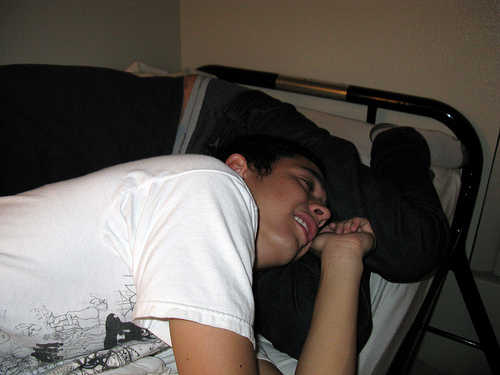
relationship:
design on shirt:
[2, 285, 171, 371] [2, 152, 276, 371]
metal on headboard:
[274, 73, 351, 104] [193, 64, 483, 370]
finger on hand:
[319, 217, 373, 234] [310, 214, 375, 252]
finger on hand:
[347, 216, 369, 234] [310, 214, 375, 252]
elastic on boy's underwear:
[173, 92, 204, 154] [172, 72, 249, 155]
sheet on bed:
[286, 100, 464, 373] [124, 60, 497, 372]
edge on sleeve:
[133, 301, 257, 349] [129, 181, 261, 344]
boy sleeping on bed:
[0, 136, 373, 375] [6, 61, 475, 370]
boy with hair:
[0, 136, 373, 375] [214, 130, 329, 175]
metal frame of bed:
[198, 60, 498, 370] [6, 61, 475, 370]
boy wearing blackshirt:
[0, 136, 373, 375] [3, 61, 158, 152]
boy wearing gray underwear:
[0, 136, 373, 375] [173, 70, 254, 163]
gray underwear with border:
[173, 70, 254, 163] [166, 72, 216, 152]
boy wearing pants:
[0, 136, 373, 375] [202, 90, 454, 356]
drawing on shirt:
[21, 300, 143, 372] [2, 152, 276, 371]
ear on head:
[224, 153, 246, 178] [216, 144, 330, 274]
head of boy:
[216, 144, 330, 274] [2, 118, 377, 372]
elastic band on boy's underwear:
[170, 70, 218, 155] [168, 64, 259, 156]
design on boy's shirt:
[0, 275, 169, 375] [199, 134, 343, 298]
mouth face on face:
[274, 152, 334, 254] [272, 157, 328, 267]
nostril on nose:
[313, 202, 323, 216] [312, 201, 331, 225]